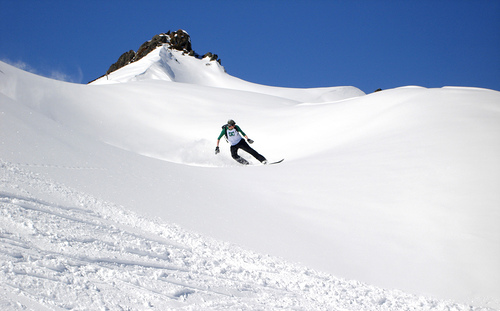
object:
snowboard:
[270, 158, 284, 164]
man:
[215, 119, 268, 165]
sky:
[5, 0, 496, 90]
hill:
[85, 29, 249, 84]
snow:
[0, 192, 497, 309]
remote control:
[214, 119, 267, 165]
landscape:
[40, 73, 284, 199]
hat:
[228, 120, 236, 128]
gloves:
[215, 147, 221, 155]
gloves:
[247, 139, 254, 144]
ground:
[0, 62, 500, 308]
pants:
[230, 138, 266, 165]